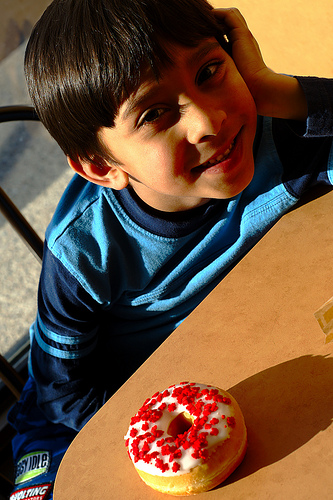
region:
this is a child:
[3, 9, 288, 374]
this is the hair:
[39, 2, 128, 97]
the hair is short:
[37, 4, 122, 92]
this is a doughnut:
[128, 371, 242, 489]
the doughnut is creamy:
[131, 375, 229, 493]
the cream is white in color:
[198, 393, 227, 437]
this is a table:
[252, 252, 317, 325]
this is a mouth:
[211, 128, 243, 171]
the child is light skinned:
[130, 130, 170, 181]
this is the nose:
[185, 106, 223, 138]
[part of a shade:
[283, 442, 295, 461]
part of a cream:
[196, 421, 218, 450]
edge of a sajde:
[268, 437, 297, 470]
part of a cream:
[179, 418, 217, 470]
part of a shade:
[267, 444, 288, 472]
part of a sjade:
[256, 431, 285, 470]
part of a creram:
[185, 430, 198, 447]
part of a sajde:
[243, 440, 275, 488]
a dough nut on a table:
[122, 371, 245, 490]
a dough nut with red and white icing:
[122, 374, 252, 493]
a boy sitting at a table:
[5, 1, 330, 497]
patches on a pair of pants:
[6, 441, 60, 497]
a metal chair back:
[0, 89, 56, 263]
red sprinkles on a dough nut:
[119, 380, 240, 473]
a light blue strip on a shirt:
[14, 243, 110, 365]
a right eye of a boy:
[128, 97, 188, 133]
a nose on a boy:
[179, 98, 234, 143]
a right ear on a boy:
[65, 139, 129, 199]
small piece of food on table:
[91, 366, 279, 491]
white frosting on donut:
[194, 397, 229, 436]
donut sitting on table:
[79, 375, 249, 497]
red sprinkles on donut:
[190, 408, 224, 445]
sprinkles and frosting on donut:
[186, 390, 234, 442]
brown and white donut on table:
[195, 426, 236, 486]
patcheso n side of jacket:
[11, 447, 53, 484]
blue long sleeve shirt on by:
[9, 215, 146, 367]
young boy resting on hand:
[12, 9, 314, 244]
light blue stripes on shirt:
[21, 321, 76, 372]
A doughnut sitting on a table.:
[114, 375, 246, 495]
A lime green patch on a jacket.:
[10, 446, 50, 484]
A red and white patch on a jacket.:
[7, 481, 52, 499]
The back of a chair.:
[0, 99, 80, 261]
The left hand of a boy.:
[209, 3, 264, 118]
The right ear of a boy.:
[61, 142, 128, 189]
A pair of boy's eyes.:
[138, 57, 226, 125]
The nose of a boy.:
[179, 87, 226, 143]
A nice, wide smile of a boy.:
[192, 122, 246, 174]